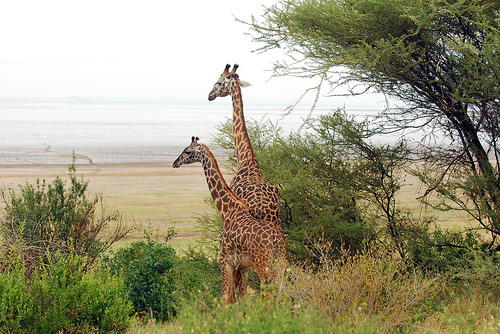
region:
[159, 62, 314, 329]
two giraffes are watching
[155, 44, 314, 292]
two giraffes are watching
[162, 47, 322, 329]
two giraffes are watching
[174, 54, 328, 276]
two giraffes are watching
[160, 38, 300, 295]
two giraffes are watching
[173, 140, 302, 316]
a smaller brown giraffe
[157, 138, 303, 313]
a smaller brown giraffe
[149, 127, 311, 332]
a smaller brown giraffe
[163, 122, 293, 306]
a smaller brown giraffe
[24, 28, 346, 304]
two giraffe in the wild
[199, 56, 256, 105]
the head of a giraffe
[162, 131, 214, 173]
the head of a giraffe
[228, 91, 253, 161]
the neck of a giraffe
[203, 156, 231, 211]
the neck of a giraffe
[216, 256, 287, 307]
the legs of a giraffe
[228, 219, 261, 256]
the spots of a giraffe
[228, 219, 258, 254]
the fur of a giraffe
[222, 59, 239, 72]
the horns of a giraffe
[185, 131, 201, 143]
the horns of a giraffe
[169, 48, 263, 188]
Two giraffe's gaze into the distance.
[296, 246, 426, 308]
Dried grass near the giraffe.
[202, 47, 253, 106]
Two horns on the head of a giraffe.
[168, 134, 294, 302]
The smaller giraffe is looking outwards.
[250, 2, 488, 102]
Large green tree near a giraffe.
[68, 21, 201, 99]
Pale blue sky far above.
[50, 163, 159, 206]
Sand near the grassy plain.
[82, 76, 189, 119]
Where the land and sky meet.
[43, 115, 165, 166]
Calm water in front of the animals.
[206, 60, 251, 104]
the head of a giraffe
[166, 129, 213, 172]
the head of a giraffe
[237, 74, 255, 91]
the ear of a giraffe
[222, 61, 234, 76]
a horn of a giraffe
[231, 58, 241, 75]
a horn of a giraffe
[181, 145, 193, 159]
an eye of a giraffe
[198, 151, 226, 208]
the neck of a giraffe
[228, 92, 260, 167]
the neck of a giraffe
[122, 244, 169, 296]
the leaves of a tree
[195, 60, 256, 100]
head of a giraffe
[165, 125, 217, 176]
head of a giraffe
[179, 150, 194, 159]
eye of a giraffe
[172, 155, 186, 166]
mouth of a giraffe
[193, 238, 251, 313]
leg of a giraffe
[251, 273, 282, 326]
leg of a giraffe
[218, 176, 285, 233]
body of a giraffe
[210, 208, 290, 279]
body of a giraffe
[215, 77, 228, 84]
an eye of a giraffe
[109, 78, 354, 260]
these are two giraffes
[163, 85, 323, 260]
the giraffes are tall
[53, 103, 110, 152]
the sky is hazy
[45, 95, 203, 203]
the horizon is gray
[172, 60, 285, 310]
the giraffes are standing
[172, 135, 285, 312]
the horns on the giraffe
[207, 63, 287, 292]
the giraffe is tall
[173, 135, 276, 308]
the giraffe is short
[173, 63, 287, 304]
the giraffes are standing together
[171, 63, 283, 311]
the giraffes have manes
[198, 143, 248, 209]
the mane is brown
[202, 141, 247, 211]
the mane is short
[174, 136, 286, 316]
the giraffe has short horns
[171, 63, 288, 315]
the giraffes are standing